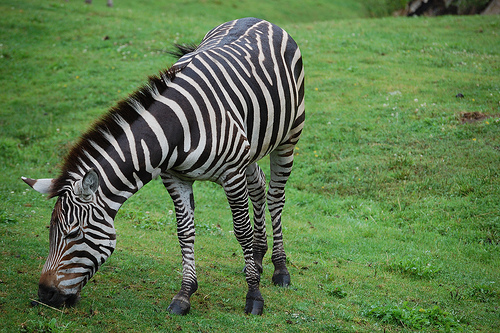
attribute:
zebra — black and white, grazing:
[21, 17, 306, 315]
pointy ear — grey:
[70, 170, 99, 202]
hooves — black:
[164, 260, 251, 331]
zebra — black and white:
[18, 19, 400, 317]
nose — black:
[36, 280, 80, 310]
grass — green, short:
[10, 28, 100, 113]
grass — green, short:
[0, 0, 499, 332]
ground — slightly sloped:
[0, 0, 499, 331]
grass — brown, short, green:
[318, 38, 469, 140]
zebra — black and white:
[2, 10, 334, 317]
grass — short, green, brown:
[308, 51, 438, 193]